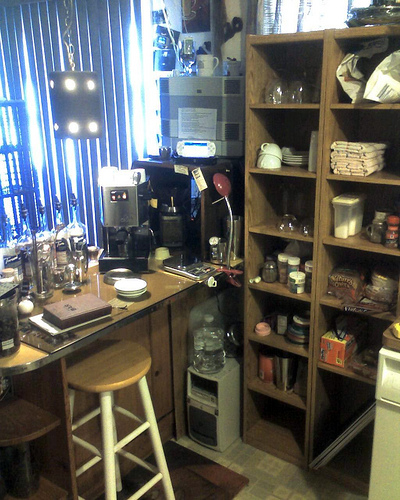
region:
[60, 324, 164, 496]
a tall wooden chair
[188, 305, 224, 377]
a large water bottle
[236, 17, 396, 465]
a shelf full of items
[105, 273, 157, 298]
a stack of plates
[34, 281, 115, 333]
a red cased book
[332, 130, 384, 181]
a group of towels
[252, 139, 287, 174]
two white cups stacked together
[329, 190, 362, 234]
a container with sugar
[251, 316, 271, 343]
a small pink cup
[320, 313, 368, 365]
a napkin box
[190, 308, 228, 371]
Water jug on top of PC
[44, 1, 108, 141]
Lamp above desk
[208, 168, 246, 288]
Red clip lamp by white mugs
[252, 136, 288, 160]
White mug stacked on top of another white mug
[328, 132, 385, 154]
Kitchen towelette is folded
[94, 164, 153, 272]
Espresso machine on table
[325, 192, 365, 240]
Plastic container with sugar in it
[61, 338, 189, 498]
Stool underneath counter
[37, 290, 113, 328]
Old book on top of counter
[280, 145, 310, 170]
White plates stacked by white mugs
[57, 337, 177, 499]
a wooden stool under the counter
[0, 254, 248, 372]
a cluttered counter top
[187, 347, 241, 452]
a white computer tower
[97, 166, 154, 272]
a coffee maker on the counter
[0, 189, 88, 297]
bottles of flavored syrup on the counter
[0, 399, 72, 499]
empty shelves under the counter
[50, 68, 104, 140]
a decorative light hanging from the ceiling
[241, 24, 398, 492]
wooden shelves full of various objects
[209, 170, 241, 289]
a small red desk lamp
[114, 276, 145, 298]
a small stack of bowls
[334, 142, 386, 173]
stack of kitchen towels on shelf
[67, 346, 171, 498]
white and brown bar stool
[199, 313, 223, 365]
clear jug of water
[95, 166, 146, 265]
silver and grey coffee maker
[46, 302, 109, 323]
brown book on top of other books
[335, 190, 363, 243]
small canister of sugar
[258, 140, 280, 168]
two white coffee mugs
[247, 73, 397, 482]
wooden kitchen shelves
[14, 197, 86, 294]
bottles on countertop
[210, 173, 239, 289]
lamp attached to side of countertop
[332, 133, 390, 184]
A stack of dish towels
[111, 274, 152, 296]
A stack of saucers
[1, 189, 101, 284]
Empty glass bottles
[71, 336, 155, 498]
White and tan barstool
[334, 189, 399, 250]
Spices on a shelf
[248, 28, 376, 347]
Pantries with many items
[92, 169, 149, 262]
Coffee Machine that is silver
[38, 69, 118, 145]
light fixture with four holes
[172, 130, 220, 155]
Clock with many buttons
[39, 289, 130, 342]
Stacked books on counter